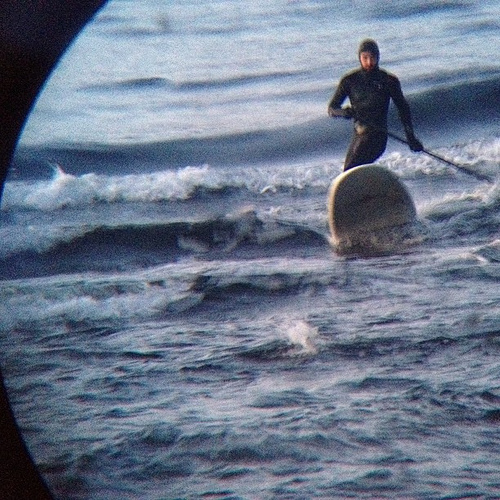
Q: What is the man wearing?
A: A black wetsuit.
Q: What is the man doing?
A: Wakeboarding.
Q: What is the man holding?
A: A rope.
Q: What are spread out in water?
A: Ripples.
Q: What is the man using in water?
A: Black paddle.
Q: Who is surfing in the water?
A: Skinny man.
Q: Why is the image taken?
A: Remembrance.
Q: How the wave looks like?
A: Rushy.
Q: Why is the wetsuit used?
A: In water.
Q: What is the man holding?
A: Black paddle.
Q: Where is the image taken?
A: In water.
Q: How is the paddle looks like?
A: Wet.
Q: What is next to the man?
A: Wave.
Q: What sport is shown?
A: Paddleboarding.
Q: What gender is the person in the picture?
A: Male.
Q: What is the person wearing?
A: Wetsuit.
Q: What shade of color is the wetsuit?
A: Black.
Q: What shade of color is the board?
A: White.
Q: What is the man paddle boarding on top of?
A: Water.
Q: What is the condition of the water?
A: Choppy.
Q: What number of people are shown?
A: 1.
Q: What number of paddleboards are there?
A: 1.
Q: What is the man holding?
A: Paddle/oar.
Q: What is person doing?
A: Paddling.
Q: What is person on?
A: Paddle board.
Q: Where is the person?
A: In ocean.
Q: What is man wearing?
A: Wetsuit.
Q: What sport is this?
A: Paddle boarding.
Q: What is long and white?
A: Board.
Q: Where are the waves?
A: In the water.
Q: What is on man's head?
A: Wetsuit cap.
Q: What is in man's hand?
A: Paddle.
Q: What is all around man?
A: Water.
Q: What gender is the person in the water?
A: Male.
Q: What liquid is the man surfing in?
A: Water.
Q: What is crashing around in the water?
A: Waves.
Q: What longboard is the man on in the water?
A: Surfboard.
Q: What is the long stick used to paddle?
A: Paddle.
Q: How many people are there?
A: 1.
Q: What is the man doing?
A: Wakeboarding.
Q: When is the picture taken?
A: Daytime.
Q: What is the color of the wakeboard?
A: White.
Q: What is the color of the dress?
A: Black.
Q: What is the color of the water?
A: Blue.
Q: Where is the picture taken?
A: On the ocean.